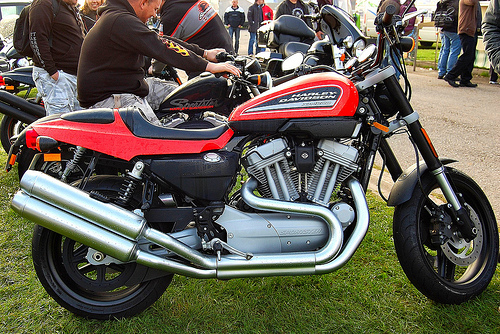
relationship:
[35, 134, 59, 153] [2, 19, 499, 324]
light in bike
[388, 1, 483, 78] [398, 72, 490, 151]
people in street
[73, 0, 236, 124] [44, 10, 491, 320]
he in bikes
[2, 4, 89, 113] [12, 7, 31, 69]
man has backpack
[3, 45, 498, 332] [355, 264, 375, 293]
ground seen part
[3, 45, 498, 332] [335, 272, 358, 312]
ground seen part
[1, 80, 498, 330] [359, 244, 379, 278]
grass seen part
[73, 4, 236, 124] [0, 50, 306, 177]
he on bike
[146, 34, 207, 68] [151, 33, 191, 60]
sleeve has logo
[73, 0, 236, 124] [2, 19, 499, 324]
he sitting on bike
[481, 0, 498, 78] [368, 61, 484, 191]
people walking on road